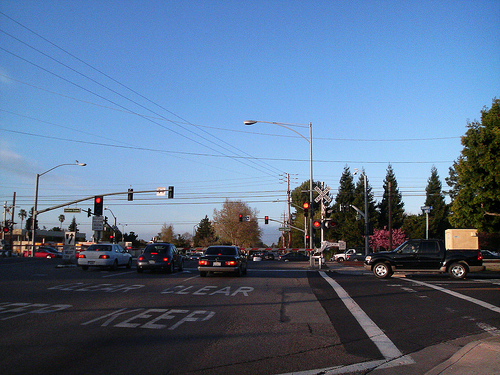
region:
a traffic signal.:
[30, 165, 182, 272]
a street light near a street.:
[241, 119, 317, 274]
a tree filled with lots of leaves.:
[430, 91, 497, 261]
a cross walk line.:
[300, 254, 408, 370]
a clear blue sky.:
[5, 0, 494, 234]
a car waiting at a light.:
[170, 236, 257, 299]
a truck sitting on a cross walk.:
[352, 219, 483, 285]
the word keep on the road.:
[82, 291, 224, 361]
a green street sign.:
[60, 198, 91, 219]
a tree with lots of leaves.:
[128, 214, 180, 274]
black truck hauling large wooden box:
[363, 226, 482, 281]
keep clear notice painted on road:
[80, 278, 256, 334]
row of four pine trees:
[331, 160, 449, 238]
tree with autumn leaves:
[211, 195, 264, 250]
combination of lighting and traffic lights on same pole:
[28, 157, 175, 262]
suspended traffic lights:
[236, 210, 272, 226]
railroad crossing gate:
[186, 243, 308, 253]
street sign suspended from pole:
[61, 206, 82, 214]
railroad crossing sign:
[1, 198, 13, 250]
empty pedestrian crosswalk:
[314, 267, 498, 373]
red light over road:
[71, 176, 121, 233]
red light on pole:
[296, 196, 313, 248]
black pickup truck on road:
[365, 234, 492, 293]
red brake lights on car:
[195, 238, 260, 293]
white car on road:
[70, 231, 137, 283]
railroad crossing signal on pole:
[306, 177, 358, 294]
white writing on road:
[76, 274, 264, 366]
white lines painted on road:
[309, 246, 496, 363]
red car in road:
[19, 240, 87, 279]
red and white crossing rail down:
[236, 233, 318, 264]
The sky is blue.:
[233, 12, 410, 95]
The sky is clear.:
[210, 15, 366, 91]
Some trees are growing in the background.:
[344, 141, 494, 215]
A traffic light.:
[80, 185, 111, 226]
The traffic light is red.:
[89, 182, 117, 227]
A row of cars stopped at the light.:
[70, 234, 262, 284]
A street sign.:
[83, 209, 110, 233]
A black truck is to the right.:
[361, 230, 492, 292]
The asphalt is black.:
[210, 316, 282, 369]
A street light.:
[235, 111, 329, 146]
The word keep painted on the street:
[85, 300, 222, 335]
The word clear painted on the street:
[160, 275, 255, 296]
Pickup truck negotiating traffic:
[356, 230, 491, 280]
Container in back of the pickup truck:
[440, 220, 480, 255]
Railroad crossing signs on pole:
[310, 180, 330, 205]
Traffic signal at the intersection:
[85, 190, 115, 215]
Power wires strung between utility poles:
[180, 180, 276, 202]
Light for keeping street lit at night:
[235, 115, 260, 130]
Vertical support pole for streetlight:
[301, 115, 312, 261]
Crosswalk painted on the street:
[311, 265, 403, 365]